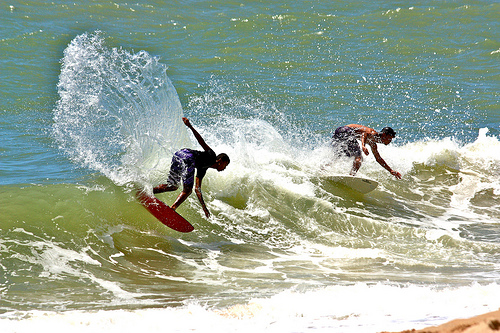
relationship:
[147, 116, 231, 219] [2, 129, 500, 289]
surfer riding wave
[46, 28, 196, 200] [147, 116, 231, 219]
splash created by surfer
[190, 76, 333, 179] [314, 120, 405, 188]
splash created by surfer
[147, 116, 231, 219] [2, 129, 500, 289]
surfer riding on wave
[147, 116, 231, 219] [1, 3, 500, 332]
surfer in water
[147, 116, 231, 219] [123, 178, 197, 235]
surfer on top of surfboard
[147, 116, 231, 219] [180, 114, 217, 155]
surfer has arm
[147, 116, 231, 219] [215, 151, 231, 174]
surfer has head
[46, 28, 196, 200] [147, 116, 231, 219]
splash behind surfer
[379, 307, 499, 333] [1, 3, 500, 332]
sand near water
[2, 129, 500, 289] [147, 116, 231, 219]
wave with surfer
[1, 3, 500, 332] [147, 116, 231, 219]
water behind surfer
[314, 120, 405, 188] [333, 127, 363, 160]
surfer has shorts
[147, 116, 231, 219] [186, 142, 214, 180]
surfer with shirt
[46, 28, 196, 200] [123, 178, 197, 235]
splash of a surfboard